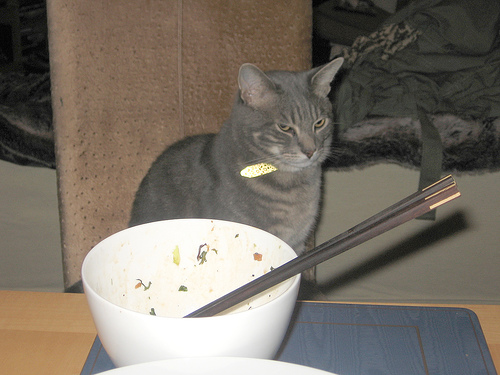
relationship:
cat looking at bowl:
[230, 69, 339, 199] [103, 227, 273, 330]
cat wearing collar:
[230, 69, 339, 199] [237, 163, 269, 182]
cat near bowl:
[230, 69, 339, 199] [103, 227, 273, 330]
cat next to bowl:
[230, 69, 339, 199] [103, 227, 273, 330]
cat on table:
[230, 69, 339, 199] [3, 290, 59, 332]